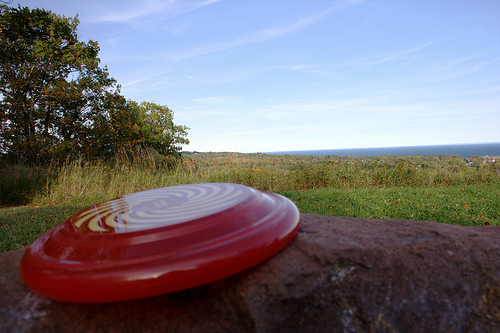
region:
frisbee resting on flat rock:
[13, 180, 493, 326]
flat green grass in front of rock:
[0, 181, 495, 241]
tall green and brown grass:
[36, 152, 493, 202]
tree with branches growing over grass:
[0, 0, 185, 165]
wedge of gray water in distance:
[260, 140, 495, 155]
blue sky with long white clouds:
[1, 0, 496, 142]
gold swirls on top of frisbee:
[67, 180, 254, 235]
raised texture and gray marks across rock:
[11, 210, 496, 330]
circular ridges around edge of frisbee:
[20, 195, 300, 300]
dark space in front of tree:
[1, 152, 41, 212]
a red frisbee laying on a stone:
[24, 168, 303, 290]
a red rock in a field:
[326, 243, 469, 315]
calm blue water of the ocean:
[354, 145, 491, 156]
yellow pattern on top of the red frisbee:
[109, 191, 209, 224]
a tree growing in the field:
[0, 16, 187, 163]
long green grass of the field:
[52, 153, 179, 188]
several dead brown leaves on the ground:
[378, 186, 495, 221]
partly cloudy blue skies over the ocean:
[258, 30, 409, 131]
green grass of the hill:
[372, 186, 462, 211]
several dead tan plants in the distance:
[191, 152, 276, 170]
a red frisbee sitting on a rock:
[19, 168, 314, 298]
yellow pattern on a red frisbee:
[73, 183, 229, 235]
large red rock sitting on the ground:
[277, 233, 443, 300]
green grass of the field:
[378, 187, 473, 219]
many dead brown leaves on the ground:
[377, 187, 498, 227]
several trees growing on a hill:
[6, 6, 176, 162]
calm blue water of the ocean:
[363, 147, 484, 157]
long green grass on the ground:
[42, 158, 177, 189]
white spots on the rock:
[321, 262, 371, 325]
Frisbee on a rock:
[79, 158, 289, 303]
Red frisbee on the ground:
[106, 195, 272, 275]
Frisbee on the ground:
[129, 188, 295, 276]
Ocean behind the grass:
[310, 119, 459, 194]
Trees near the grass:
[54, 65, 166, 145]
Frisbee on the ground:
[75, 164, 280, 291]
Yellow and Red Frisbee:
[80, 149, 234, 259]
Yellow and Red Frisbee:
[113, 190, 223, 248]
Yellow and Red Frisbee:
[69, 190, 136, 248]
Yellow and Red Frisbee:
[186, 192, 215, 212]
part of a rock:
[421, 233, 428, 239]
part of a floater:
[184, 248, 196, 262]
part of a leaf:
[124, 106, 144, 132]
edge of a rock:
[328, 304, 340, 328]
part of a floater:
[158, 269, 168, 271]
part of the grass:
[358, 150, 383, 173]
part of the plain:
[385, 180, 391, 192]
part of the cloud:
[333, 70, 355, 107]